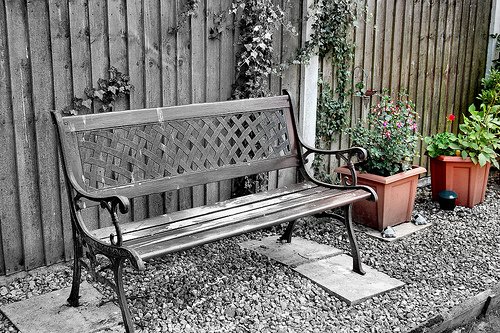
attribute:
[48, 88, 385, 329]
bench — wooden 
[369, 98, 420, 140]
flowers — pink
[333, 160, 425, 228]
pot — square 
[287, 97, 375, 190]
arm rail — decorative